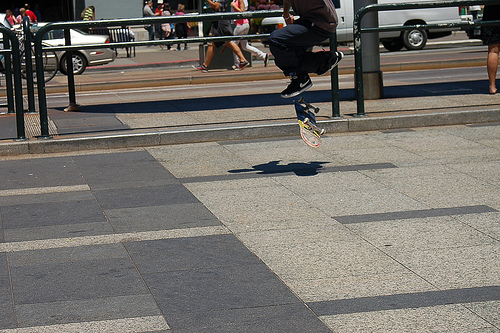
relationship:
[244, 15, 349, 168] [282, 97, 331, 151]
man flipping skateboard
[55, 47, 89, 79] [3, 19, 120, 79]
tire on sedan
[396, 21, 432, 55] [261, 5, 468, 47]
tire on truck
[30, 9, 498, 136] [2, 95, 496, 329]
railing next to ground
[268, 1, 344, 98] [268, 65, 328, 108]
man wearing shoes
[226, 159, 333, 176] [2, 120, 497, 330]
shadow cast on road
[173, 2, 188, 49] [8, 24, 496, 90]
woman running in street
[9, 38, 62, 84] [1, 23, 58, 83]
tire of bike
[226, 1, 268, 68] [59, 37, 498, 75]
person in street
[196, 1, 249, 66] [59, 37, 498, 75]
person in street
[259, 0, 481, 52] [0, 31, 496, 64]
truck in street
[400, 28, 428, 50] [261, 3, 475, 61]
tire of truck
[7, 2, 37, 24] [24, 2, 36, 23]
person wearing red top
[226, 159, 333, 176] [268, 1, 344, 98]
shadow underneath man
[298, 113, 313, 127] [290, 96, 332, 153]
wheel on skateboard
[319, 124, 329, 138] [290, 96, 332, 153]
wheel on skateboard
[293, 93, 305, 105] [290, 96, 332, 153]
wheel on skateboard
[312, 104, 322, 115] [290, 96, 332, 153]
wheel on skateboard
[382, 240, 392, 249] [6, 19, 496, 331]
spot on ground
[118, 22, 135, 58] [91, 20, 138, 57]
person sitting on bench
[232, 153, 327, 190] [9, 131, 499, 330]
shadow across ground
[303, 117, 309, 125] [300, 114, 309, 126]
wheel of skateboard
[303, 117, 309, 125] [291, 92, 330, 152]
wheel of skateboard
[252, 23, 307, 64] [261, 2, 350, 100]
knee of man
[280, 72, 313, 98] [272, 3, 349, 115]
black shoe of man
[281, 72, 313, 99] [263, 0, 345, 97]
black shoe of man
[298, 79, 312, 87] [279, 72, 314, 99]
nike emblem on shoe